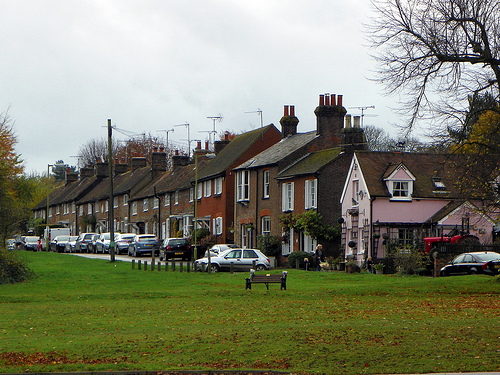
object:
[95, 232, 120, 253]
cars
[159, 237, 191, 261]
car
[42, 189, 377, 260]
row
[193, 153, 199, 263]
pole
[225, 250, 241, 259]
car window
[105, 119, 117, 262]
pole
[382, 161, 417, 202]
dog-house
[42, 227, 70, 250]
van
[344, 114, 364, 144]
chimney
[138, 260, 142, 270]
post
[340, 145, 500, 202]
roof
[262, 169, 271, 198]
windows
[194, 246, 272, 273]
car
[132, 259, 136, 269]
post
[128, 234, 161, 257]
car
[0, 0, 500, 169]
clouds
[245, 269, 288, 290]
bench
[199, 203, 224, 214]
wall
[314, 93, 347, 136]
chimney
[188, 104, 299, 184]
roof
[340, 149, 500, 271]
building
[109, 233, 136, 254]
cars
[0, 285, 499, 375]
brown leaves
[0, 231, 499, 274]
street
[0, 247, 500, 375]
grass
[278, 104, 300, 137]
chimney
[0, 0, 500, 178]
sky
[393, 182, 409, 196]
curtains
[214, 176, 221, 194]
window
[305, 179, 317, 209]
window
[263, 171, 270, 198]
window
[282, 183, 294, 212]
window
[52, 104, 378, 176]
antenna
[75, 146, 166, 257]
buildings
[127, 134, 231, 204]
roofs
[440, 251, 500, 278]
cars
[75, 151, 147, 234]
buildings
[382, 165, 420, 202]
window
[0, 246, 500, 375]
field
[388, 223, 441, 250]
dormers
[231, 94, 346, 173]
roof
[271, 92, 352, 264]
building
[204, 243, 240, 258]
car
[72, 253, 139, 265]
curb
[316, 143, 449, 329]
trim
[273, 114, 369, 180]
roof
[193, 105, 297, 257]
building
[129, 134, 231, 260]
building